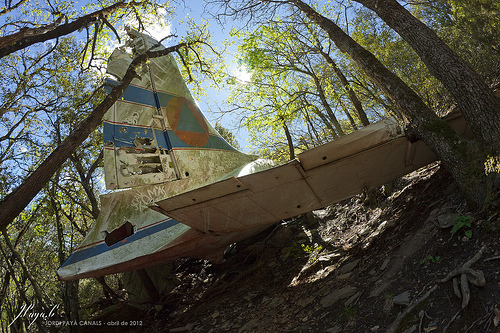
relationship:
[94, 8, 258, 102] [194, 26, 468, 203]
clouds seen through trees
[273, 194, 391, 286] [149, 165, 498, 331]
sun on ground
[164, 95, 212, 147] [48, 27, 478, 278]
circle on boat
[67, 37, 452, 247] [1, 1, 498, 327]
boat in woods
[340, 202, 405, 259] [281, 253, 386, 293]
patch of dirt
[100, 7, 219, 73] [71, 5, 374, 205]
sunlight seen through trees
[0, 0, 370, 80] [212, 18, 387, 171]
sky seen through trees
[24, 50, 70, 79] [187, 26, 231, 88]
sky with sun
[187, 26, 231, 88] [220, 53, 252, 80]
sun shining in clouds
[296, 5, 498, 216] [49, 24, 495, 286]
trunks wedge into train wreckage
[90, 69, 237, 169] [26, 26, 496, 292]
stripes on airplane tail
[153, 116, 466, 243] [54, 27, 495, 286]
wing attached to airplane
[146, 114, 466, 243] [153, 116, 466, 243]
underside belonging to wing